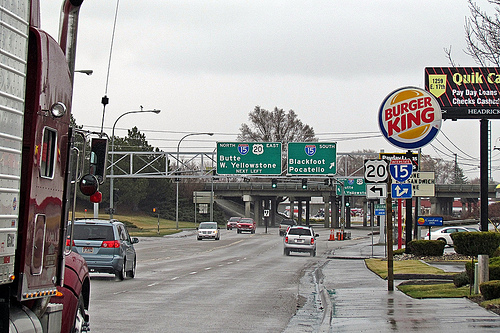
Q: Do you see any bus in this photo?
A: No, there are no buses.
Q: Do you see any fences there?
A: No, there are no fences.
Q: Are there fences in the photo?
A: No, there are no fences.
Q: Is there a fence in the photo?
A: No, there are no fences.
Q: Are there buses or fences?
A: No, there are no fences or buses.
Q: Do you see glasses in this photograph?
A: No, there are no glasses.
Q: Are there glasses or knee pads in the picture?
A: No, there are no glasses or knee pads.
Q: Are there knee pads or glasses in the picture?
A: No, there are no glasses or knee pads.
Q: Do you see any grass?
A: Yes, there is grass.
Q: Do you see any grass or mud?
A: Yes, there is grass.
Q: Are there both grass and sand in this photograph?
A: No, there is grass but no sand.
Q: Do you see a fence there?
A: No, there are no fences.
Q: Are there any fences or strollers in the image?
A: No, there are no fences or strollers.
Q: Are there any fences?
A: No, there are no fences.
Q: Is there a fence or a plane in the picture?
A: No, there are no fences or airplanes.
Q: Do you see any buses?
A: No, there are no buses.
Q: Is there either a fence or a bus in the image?
A: No, there are no buses or fences.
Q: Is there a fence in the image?
A: No, there are no fences.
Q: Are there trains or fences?
A: No, there are no fences or trains.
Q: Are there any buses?
A: No, there are no buses.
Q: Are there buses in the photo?
A: No, there are no buses.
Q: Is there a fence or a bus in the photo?
A: No, there are no buses or fences.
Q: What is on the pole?
A: The sign is on the pole.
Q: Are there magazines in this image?
A: No, there are no magazines.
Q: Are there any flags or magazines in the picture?
A: No, there are no magazines or flags.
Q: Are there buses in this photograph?
A: No, there are no buses.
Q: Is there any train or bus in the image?
A: No, there are no buses or trains.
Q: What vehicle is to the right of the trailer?
A: The vehicle is a car.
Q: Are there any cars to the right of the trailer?
A: Yes, there is a car to the right of the trailer.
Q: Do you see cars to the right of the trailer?
A: Yes, there is a car to the right of the trailer.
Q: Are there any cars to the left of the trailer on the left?
A: No, the car is to the right of the trailer.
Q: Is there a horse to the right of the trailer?
A: No, there is a car to the right of the trailer.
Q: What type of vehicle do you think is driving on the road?
A: The vehicle is a car.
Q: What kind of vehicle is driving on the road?
A: The vehicle is a car.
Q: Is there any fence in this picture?
A: No, there are no fences.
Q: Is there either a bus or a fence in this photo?
A: No, there are no fences or buses.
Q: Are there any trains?
A: No, there are no trains.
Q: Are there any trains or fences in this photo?
A: No, there are no trains or fences.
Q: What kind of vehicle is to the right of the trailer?
A: The vehicle is a car.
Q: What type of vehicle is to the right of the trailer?
A: The vehicle is a car.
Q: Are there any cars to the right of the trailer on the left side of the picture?
A: Yes, there is a car to the right of the trailer.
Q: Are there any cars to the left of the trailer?
A: No, the car is to the right of the trailer.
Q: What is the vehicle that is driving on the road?
A: The vehicle is a car.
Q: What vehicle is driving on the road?
A: The vehicle is a car.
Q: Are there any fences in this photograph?
A: No, there are no fences.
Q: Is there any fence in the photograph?
A: No, there are no fences.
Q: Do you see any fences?
A: No, there are no fences.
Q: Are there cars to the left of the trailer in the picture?
A: No, the car is to the right of the trailer.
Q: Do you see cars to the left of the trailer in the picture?
A: No, the car is to the right of the trailer.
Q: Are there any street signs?
A: Yes, there is a street sign.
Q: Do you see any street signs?
A: Yes, there is a street sign.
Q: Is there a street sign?
A: Yes, there is a street sign.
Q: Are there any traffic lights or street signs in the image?
A: Yes, there is a street sign.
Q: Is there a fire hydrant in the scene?
A: No, there are no fire hydrants.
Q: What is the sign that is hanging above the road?
A: The sign is a street sign.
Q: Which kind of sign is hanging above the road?
A: The sign is a street sign.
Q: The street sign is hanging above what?
A: The street sign is hanging above the road.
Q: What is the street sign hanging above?
A: The street sign is hanging above the road.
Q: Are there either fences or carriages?
A: No, there are no fences or carriages.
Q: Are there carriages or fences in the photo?
A: No, there are no fences or carriages.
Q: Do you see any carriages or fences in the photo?
A: No, there are no fences or carriages.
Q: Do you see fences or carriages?
A: No, there are no fences or carriages.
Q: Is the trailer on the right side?
A: No, the trailer is on the left of the image.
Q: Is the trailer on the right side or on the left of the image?
A: The trailer is on the left of the image.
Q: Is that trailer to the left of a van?
A: No, the trailer is to the left of a car.